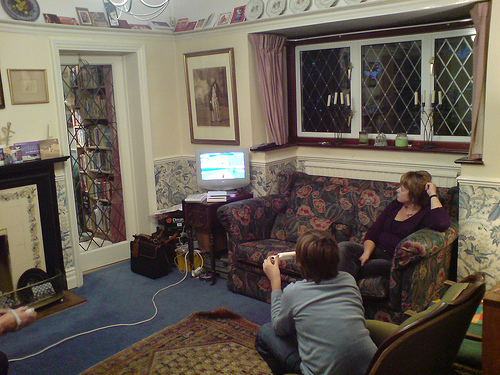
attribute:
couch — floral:
[215, 169, 461, 320]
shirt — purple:
[364, 197, 446, 253]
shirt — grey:
[270, 275, 386, 374]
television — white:
[195, 150, 250, 190]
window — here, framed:
[288, 29, 480, 147]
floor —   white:
[4, 259, 268, 374]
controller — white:
[269, 249, 304, 262]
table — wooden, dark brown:
[179, 194, 247, 279]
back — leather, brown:
[384, 295, 486, 374]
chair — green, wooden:
[340, 268, 484, 374]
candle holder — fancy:
[326, 104, 351, 143]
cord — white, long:
[9, 246, 203, 369]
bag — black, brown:
[129, 235, 172, 278]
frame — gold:
[184, 52, 241, 146]